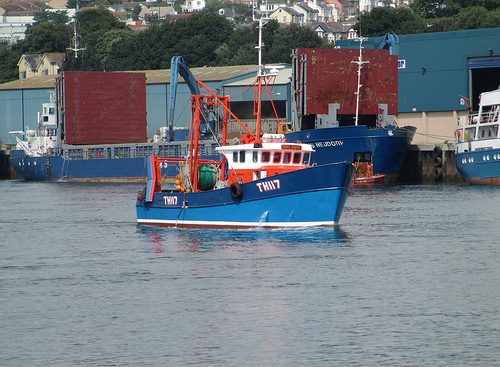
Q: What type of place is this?
A: It is a lake.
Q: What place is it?
A: It is a lake.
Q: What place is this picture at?
A: It is at the lake.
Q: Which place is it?
A: It is a lake.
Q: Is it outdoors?
A: Yes, it is outdoors.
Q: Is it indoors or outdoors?
A: It is outdoors.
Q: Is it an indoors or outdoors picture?
A: It is outdoors.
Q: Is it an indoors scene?
A: No, it is outdoors.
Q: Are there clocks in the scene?
A: No, there are no clocks.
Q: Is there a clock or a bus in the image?
A: No, there are no clocks or buses.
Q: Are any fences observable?
A: No, there are no fences.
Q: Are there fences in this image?
A: No, there are no fences.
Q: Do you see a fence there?
A: No, there are no fences.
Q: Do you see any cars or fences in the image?
A: No, there are no fences or cars.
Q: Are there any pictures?
A: No, there are no pictures.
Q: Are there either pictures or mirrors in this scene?
A: No, there are no pictures or mirrors.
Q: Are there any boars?
A: Yes, there is a boar.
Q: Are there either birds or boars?
A: Yes, there is a boar.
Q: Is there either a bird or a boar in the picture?
A: Yes, there is a boar.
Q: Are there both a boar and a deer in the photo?
A: No, there is a boar but no deer.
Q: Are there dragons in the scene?
A: No, there are no dragons.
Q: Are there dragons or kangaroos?
A: No, there are no dragons or kangaroos.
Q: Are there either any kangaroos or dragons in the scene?
A: No, there are no dragons or kangaroos.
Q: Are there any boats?
A: Yes, there is a boat.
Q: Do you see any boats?
A: Yes, there is a boat.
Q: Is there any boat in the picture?
A: Yes, there is a boat.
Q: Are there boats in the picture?
A: Yes, there is a boat.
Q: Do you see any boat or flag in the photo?
A: Yes, there is a boat.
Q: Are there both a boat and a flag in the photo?
A: No, there is a boat but no flags.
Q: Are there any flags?
A: No, there are no flags.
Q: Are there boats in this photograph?
A: Yes, there is a boat.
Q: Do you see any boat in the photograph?
A: Yes, there is a boat.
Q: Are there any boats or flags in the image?
A: Yes, there is a boat.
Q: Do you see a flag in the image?
A: No, there are no flags.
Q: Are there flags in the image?
A: No, there are no flags.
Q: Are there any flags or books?
A: No, there are no flags or books.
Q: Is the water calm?
A: Yes, the water is calm.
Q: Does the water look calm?
A: Yes, the water is calm.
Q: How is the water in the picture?
A: The water is calm.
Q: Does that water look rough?
A: No, the water is calm.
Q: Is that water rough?
A: No, the water is calm.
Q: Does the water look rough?
A: No, the water is calm.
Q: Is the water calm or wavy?
A: The water is calm.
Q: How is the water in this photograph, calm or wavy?
A: The water is calm.